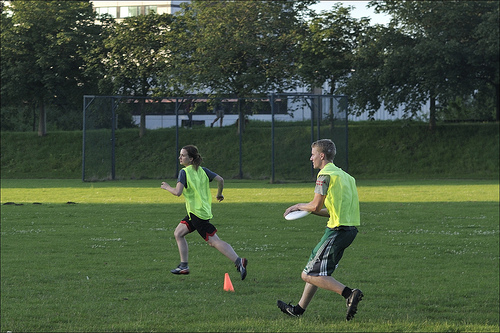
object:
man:
[274, 138, 364, 323]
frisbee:
[283, 210, 313, 221]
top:
[181, 164, 213, 221]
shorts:
[302, 226, 360, 277]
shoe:
[345, 287, 364, 321]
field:
[0, 176, 500, 333]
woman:
[159, 144, 248, 282]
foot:
[236, 257, 248, 281]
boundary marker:
[223, 272, 236, 293]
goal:
[81, 93, 349, 185]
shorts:
[180, 212, 219, 241]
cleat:
[276, 298, 305, 319]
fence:
[318, 92, 349, 123]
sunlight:
[0, 184, 500, 205]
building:
[110, 0, 475, 131]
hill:
[0, 120, 500, 179]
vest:
[316, 162, 360, 229]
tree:
[169, 0, 309, 128]